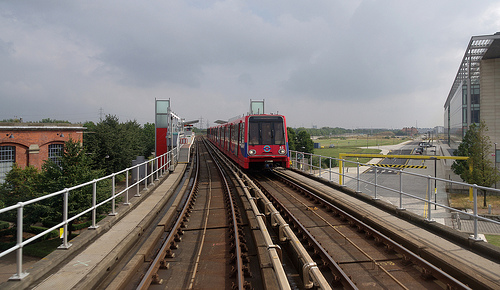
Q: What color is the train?
A: Red.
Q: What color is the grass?
A: Green.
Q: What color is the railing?
A: Gray.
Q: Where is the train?
A: On the tracks.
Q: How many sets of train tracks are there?
A: Two.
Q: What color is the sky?
A: Grey.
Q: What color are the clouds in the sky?
A: Grey.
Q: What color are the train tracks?
A: Brown.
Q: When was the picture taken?
A: Daytime.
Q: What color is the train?
A: Red.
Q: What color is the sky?
A: Gray.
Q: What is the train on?
A: Train tracks.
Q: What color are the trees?
A: Green.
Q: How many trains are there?
A: One.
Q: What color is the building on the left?
A: Red.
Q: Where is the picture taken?
A: On the train tracks.